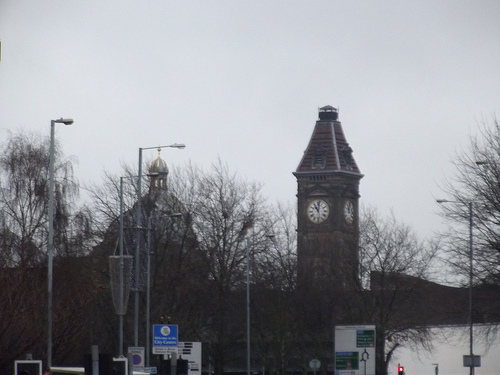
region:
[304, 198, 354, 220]
A clock on the tower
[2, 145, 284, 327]
Trees by the clocktower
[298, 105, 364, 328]
A clocktower near the trees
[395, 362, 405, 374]
A traffic light below the tower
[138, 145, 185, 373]
A lamp post by the trees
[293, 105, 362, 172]
The roof of the clocktower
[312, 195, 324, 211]
The hands on the clock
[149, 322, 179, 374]
A sign below the lamp post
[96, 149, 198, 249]
The roof of the building behind the trees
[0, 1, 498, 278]
The sky above the clock tower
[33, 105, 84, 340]
light post high in the air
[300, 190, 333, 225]
white clock on the tower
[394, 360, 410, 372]
red light lit up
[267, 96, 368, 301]
stone tower behind the trees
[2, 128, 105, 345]
trees with no leaves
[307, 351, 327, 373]
back of a stop sign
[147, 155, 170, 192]
dome on top of a building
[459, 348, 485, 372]
back of sign on a pole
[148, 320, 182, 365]
blue and white sign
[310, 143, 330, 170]
window in the top of the tower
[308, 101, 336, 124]
round top of clock tower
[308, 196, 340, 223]
white face on clock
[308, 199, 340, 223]
black roman numerals on clock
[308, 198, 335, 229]
black hands on clock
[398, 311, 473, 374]
white snow near clock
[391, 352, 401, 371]
red traffic light under clock tower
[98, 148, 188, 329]
tall and grey light poles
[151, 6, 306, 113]
sky is grey and cloudy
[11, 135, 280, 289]
tall and bare trees left of clock tower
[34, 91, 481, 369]
a picture of a city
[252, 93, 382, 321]
a clock tower in the shot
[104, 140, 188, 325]
a street light in the area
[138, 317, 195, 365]
a sign on the street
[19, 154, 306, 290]
the trees do not have leaves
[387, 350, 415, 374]
a red light for traffic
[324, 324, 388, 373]
signs on a building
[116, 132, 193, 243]
a structure in the background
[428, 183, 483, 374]
a light pole near the street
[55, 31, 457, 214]
a cloudy day over the city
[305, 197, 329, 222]
A white clock face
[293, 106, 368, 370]
A tall brick clock tower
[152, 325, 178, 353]
A welcome sign to the sity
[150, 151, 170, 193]
A large tower behind the trees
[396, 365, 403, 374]
A lit up traffic light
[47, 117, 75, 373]
A tall lamp post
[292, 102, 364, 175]
The top of the clock tower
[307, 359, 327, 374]
A small stop sign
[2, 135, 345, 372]
Bare trees by the road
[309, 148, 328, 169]
A window on the clock tower